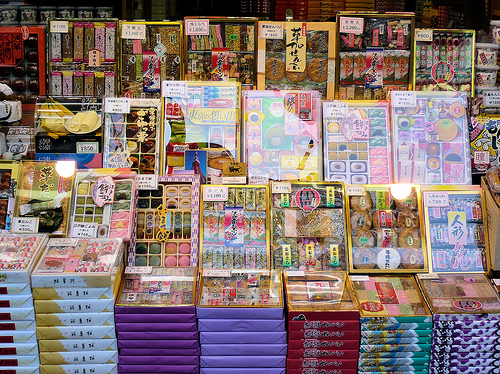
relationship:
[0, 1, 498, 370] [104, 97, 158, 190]
stand has magazines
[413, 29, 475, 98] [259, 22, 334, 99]
box has bananas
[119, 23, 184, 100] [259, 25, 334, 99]
package on top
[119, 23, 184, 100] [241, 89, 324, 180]
package in middle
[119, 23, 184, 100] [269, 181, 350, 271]
package on bottom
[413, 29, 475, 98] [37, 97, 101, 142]
box has candies